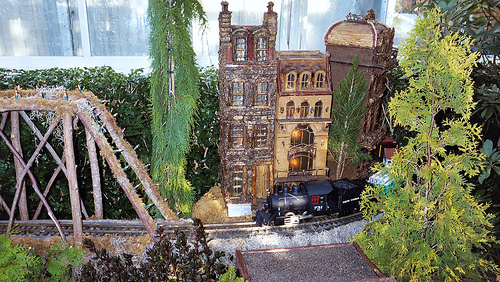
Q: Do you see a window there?
A: Yes, there are windows.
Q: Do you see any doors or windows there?
A: Yes, there are windows.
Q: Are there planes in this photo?
A: No, there are no planes.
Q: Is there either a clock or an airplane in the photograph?
A: No, there are no airplanes or clocks.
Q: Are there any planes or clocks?
A: No, there are no planes or clocks.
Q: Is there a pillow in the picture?
A: No, there are no pillows.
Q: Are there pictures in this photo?
A: No, there are no pictures.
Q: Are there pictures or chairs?
A: No, there are no pictures or chairs.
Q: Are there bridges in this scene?
A: Yes, there is a bridge.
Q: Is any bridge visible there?
A: Yes, there is a bridge.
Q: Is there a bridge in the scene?
A: Yes, there is a bridge.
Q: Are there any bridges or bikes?
A: Yes, there is a bridge.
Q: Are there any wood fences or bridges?
A: Yes, there is a wood bridge.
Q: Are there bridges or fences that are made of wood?
A: Yes, the bridge is made of wood.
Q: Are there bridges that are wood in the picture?
A: Yes, there is a wood bridge.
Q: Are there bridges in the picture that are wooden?
A: Yes, there is a bridge that is wooden.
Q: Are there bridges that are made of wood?
A: Yes, there is a bridge that is made of wood.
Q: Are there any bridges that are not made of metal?
A: Yes, there is a bridge that is made of wood.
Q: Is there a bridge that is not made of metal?
A: Yes, there is a bridge that is made of wood.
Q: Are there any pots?
A: No, there are no pots.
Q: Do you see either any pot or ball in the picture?
A: No, there are no pots or balls.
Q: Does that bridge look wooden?
A: Yes, the bridge is wooden.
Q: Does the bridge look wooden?
A: Yes, the bridge is wooden.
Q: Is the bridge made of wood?
A: Yes, the bridge is made of wood.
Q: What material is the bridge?
A: The bridge is made of wood.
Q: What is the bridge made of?
A: The bridge is made of wood.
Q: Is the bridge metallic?
A: No, the bridge is wooden.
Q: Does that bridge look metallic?
A: No, the bridge is wooden.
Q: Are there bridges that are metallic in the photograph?
A: No, there is a bridge but it is wooden.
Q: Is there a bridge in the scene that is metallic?
A: No, there is a bridge but it is wooden.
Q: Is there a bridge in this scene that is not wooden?
A: No, there is a bridge but it is wooden.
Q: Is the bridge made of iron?
A: No, the bridge is made of wood.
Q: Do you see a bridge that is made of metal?
A: No, there is a bridge but it is made of wood.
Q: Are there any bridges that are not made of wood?
A: No, there is a bridge but it is made of wood.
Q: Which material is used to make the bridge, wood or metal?
A: The bridge is made of wood.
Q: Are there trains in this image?
A: Yes, there is a train.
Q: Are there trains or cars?
A: Yes, there is a train.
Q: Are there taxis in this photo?
A: No, there are no taxis.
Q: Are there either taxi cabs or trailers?
A: No, there are no taxi cabs or trailers.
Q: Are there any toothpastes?
A: No, there are no toothpastes.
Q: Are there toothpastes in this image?
A: No, there are no toothpastes.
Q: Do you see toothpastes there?
A: No, there are no toothpastes.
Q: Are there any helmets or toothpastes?
A: No, there are no toothpastes or helmets.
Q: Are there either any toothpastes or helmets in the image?
A: No, there are no toothpastes or helmets.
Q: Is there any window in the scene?
A: Yes, there is a window.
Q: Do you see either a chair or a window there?
A: Yes, there is a window.